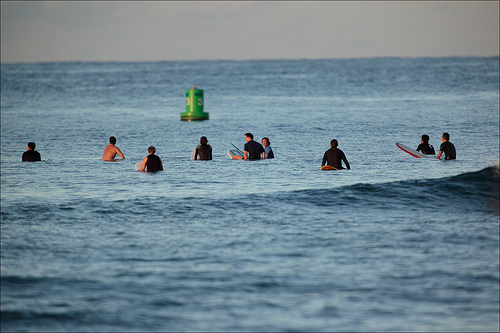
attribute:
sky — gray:
[157, 1, 269, 49]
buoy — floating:
[180, 87, 205, 122]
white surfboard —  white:
[395, 137, 428, 162]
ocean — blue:
[3, 55, 497, 332]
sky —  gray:
[4, 5, 499, 70]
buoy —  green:
[163, 75, 218, 135]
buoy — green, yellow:
[177, 84, 212, 122]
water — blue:
[2, 179, 499, 331]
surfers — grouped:
[77, 110, 393, 203]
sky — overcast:
[90, 7, 405, 47]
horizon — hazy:
[140, 73, 460, 121]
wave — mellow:
[162, 174, 490, 214]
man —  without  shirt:
[99, 134, 128, 161]